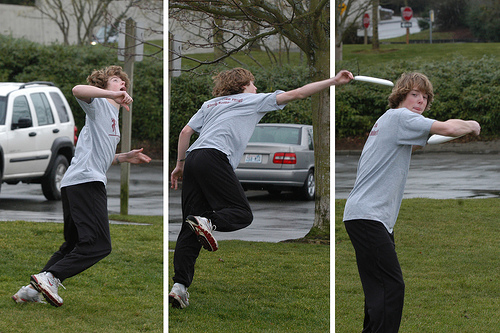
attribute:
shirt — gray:
[344, 104, 410, 229]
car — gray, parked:
[225, 113, 326, 202]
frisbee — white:
[423, 128, 466, 144]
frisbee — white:
[352, 74, 395, 86]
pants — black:
[346, 212, 405, 332]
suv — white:
[1, 86, 76, 203]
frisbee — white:
[351, 69, 391, 86]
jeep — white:
[0, 80, 77, 201]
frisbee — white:
[340, 71, 402, 93]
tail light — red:
[273, 151, 298, 164]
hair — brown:
[386, 69, 435, 109]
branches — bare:
[11, 3, 329, 61]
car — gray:
[223, 114, 330, 212]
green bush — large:
[336, 56, 498, 135]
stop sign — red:
[392, 3, 415, 20]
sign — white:
[369, 16, 429, 74]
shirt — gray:
[54, 94, 126, 191]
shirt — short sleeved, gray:
[350, 103, 457, 244]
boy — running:
[13, 65, 123, 306]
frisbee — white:
[428, 125, 481, 146]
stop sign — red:
[399, 2, 417, 21]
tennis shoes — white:
[27, 269, 72, 307]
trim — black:
[13, 153, 52, 171]